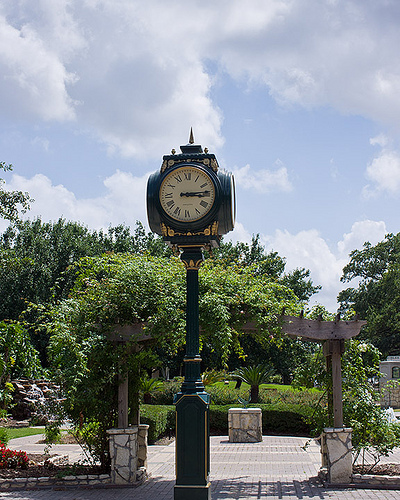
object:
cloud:
[64, 36, 226, 157]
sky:
[0, 0, 400, 317]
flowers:
[0, 443, 31, 465]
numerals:
[163, 189, 175, 199]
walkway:
[4, 406, 400, 500]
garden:
[0, 220, 400, 499]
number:
[199, 199, 210, 210]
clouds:
[0, 14, 81, 125]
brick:
[363, 486, 381, 498]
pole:
[171, 247, 213, 499]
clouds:
[334, 218, 399, 262]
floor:
[0, 407, 400, 498]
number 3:
[200, 188, 212, 198]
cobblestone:
[107, 428, 138, 486]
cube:
[146, 152, 236, 244]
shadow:
[209, 475, 328, 499]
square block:
[226, 403, 264, 444]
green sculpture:
[235, 397, 249, 407]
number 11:
[173, 171, 183, 182]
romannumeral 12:
[184, 172, 193, 180]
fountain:
[10, 374, 79, 428]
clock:
[158, 162, 218, 225]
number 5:
[193, 206, 205, 219]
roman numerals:
[166, 198, 176, 210]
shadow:
[0, 474, 175, 499]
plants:
[16, 251, 305, 470]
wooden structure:
[95, 304, 372, 430]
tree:
[336, 229, 400, 364]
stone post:
[139, 424, 148, 468]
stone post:
[318, 423, 355, 488]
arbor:
[104, 309, 369, 429]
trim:
[178, 379, 208, 397]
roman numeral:
[193, 174, 202, 183]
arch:
[128, 320, 325, 355]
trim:
[175, 241, 210, 256]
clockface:
[158, 163, 217, 221]